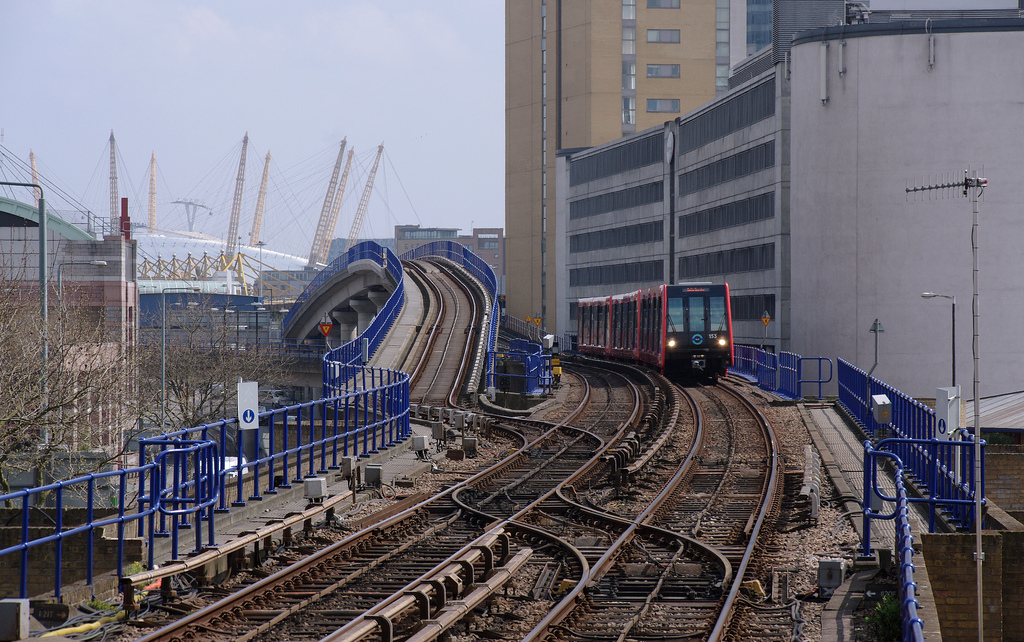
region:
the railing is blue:
[835, 353, 985, 635]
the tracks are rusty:
[122, 345, 791, 639]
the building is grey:
[554, 16, 1022, 422]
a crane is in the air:
[225, 132, 254, 265]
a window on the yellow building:
[648, 59, 683, 83]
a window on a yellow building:
[643, 89, 679, 115]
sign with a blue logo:
[235, 379, 261, 428]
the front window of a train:
[665, 294, 684, 329]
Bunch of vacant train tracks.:
[251, 525, 578, 624]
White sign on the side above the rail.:
[204, 364, 271, 437]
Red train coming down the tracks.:
[558, 280, 751, 379]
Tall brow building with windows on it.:
[500, 7, 739, 355]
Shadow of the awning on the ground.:
[898, 449, 1000, 577]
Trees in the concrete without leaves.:
[20, 309, 292, 426]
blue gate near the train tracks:
[827, 346, 986, 511]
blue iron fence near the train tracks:
[0, 376, 428, 586]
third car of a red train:
[570, 295, 606, 353]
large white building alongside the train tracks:
[549, 26, 1021, 432]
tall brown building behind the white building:
[499, 0, 709, 349]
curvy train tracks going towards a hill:
[445, 392, 736, 639]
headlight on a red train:
[709, 330, 732, 353]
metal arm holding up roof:
[305, 128, 345, 264]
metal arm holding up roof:
[248, 147, 271, 247]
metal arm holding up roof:
[223, 125, 249, 243]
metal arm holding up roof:
[140, 144, 159, 227]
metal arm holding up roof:
[105, 122, 115, 240]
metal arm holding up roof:
[23, 140, 40, 205]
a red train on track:
[541, 221, 764, 427]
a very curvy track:
[262, 208, 756, 639]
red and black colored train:
[571, 268, 749, 380]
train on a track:
[565, 269, 742, 387]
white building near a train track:
[547, 9, 1022, 417]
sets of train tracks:
[103, 244, 812, 638]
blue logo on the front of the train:
[686, 328, 709, 347]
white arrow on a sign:
[245, 408, 252, 424]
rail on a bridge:
[275, 234, 506, 408]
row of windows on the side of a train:
[572, 298, 665, 346]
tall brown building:
[496, 0, 730, 355]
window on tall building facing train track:
[647, 0, 679, 12]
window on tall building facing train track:
[642, 61, 679, 79]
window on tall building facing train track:
[641, 95, 682, 112]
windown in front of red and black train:
[665, 295, 687, 331]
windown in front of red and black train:
[685, 290, 707, 333]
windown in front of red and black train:
[708, 293, 726, 332]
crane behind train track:
[345, 142, 389, 252]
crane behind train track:
[305, 135, 349, 270]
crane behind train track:
[315, 144, 359, 267]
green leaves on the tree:
[204, 348, 230, 387]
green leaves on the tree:
[263, 344, 280, 363]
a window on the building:
[763, 241, 779, 274]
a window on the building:
[747, 228, 760, 270]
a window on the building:
[735, 260, 752, 292]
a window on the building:
[677, 224, 717, 272]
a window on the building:
[640, 266, 651, 279]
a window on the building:
[618, 250, 631, 270]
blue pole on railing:
[18, 493, 29, 591]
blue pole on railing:
[53, 483, 63, 589]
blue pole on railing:
[81, 470, 100, 573]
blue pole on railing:
[114, 468, 128, 574]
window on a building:
[565, 152, 584, 188]